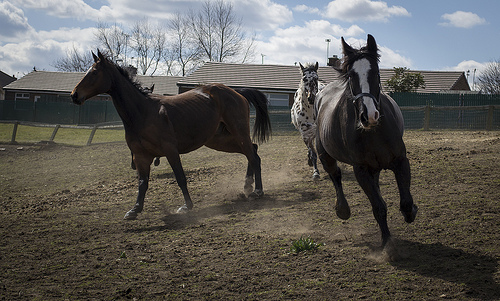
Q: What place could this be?
A: It is a field.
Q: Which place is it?
A: It is a field.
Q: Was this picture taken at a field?
A: Yes, it was taken in a field.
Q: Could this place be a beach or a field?
A: It is a field.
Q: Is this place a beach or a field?
A: It is a field.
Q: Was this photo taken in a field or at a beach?
A: It was taken at a field.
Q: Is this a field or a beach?
A: It is a field.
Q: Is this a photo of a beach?
A: No, the picture is showing a field.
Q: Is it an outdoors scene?
A: Yes, it is outdoors.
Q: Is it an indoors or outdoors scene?
A: It is outdoors.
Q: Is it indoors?
A: No, it is outdoors.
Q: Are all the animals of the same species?
A: Yes, all the animals are horses.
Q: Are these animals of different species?
A: No, all the animals are horses.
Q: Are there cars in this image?
A: No, there are no cars.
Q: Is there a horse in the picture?
A: Yes, there is a horse.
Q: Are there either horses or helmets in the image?
A: Yes, there is a horse.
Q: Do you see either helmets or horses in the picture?
A: Yes, there is a horse.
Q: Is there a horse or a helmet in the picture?
A: Yes, there is a horse.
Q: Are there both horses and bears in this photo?
A: No, there is a horse but no bears.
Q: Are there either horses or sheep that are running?
A: Yes, the horse is running.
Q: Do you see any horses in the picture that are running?
A: Yes, there is a horse that is running.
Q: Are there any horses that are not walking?
A: Yes, there is a horse that is running.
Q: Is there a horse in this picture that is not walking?
A: Yes, there is a horse that is running.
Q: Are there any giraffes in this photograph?
A: No, there are no giraffes.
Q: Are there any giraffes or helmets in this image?
A: No, there are no giraffes or helmets.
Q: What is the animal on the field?
A: The animal is a horse.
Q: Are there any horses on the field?
A: Yes, there is a horse on the field.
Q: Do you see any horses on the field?
A: Yes, there is a horse on the field.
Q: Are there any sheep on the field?
A: No, there is a horse on the field.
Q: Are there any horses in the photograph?
A: Yes, there is a horse.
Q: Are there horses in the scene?
A: Yes, there is a horse.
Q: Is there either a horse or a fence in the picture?
A: Yes, there is a horse.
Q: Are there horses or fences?
A: Yes, there is a horse.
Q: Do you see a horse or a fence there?
A: Yes, there is a horse.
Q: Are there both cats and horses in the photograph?
A: No, there is a horse but no cats.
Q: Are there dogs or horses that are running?
A: Yes, the horse is running.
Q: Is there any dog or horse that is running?
A: Yes, the horse is running.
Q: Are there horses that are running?
A: Yes, there is a horse that is running.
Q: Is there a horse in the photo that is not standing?
A: Yes, there is a horse that is running.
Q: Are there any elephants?
A: No, there are no elephants.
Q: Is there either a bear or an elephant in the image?
A: No, there are no elephants or bears.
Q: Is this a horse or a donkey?
A: This is a horse.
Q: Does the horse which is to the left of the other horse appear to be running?
A: Yes, the horse is running.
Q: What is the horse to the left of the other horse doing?
A: The horse is running.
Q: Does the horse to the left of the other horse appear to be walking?
A: No, the horse is running.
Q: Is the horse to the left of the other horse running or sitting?
A: The horse is running.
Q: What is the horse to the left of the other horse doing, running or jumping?
A: The horse is running.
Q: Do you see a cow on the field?
A: No, there is a horse on the field.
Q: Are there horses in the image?
A: Yes, there is a horse.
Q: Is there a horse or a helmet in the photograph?
A: Yes, there is a horse.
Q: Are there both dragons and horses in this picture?
A: No, there is a horse but no dragons.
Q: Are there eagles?
A: No, there are no eagles.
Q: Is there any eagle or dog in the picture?
A: No, there are no eagles or dogs.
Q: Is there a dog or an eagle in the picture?
A: No, there are no eagles or dogs.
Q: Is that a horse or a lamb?
A: That is a horse.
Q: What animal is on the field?
A: The horse is on the field.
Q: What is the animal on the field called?
A: The animal is a horse.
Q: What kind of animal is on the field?
A: The animal is a horse.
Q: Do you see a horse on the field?
A: Yes, there is a horse on the field.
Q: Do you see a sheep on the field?
A: No, there is a horse on the field.